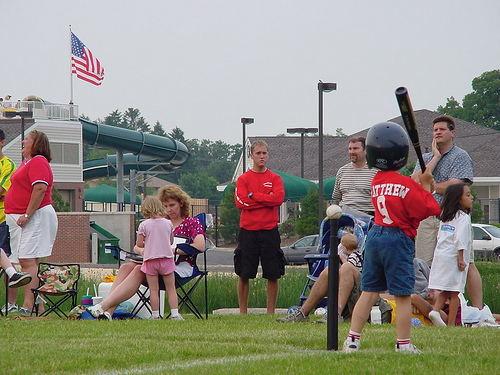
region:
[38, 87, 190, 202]
green enclosed water slide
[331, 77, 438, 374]
little boy batting ball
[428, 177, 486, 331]
little girl wearing white shirt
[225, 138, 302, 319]
teenage boy wearing long sleeve red shirt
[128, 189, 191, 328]
little girl dressed all in pink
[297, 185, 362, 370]
baseball sitting on T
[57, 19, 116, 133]
American flag waving in the air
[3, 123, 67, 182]
lady laughing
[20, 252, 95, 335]
child size camouflage chair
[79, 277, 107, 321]
reusable drinking cups with straws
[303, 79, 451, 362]
Little boy with red shirt playing T-ball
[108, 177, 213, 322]
Little girl wearing pink shirt talking to her mother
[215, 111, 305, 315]
Man standing on the side with his two arms folded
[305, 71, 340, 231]
black street light pole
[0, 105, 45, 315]
Woman standing on the side laughing so hard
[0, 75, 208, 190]
green water slide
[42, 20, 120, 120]
US flag on the top of the water slide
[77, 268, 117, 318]
water cooler on the grass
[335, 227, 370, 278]
baby standing on his fathers lap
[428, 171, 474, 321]
little girl wearing only socks without shoes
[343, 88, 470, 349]
The boy has a bat in his hand.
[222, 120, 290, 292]
The man has his hand folded.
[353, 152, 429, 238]
The boy has on a red shirt with the number 9 on it.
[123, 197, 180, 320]
the little girl has on a pink shirt and shorts.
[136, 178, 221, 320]
The lady is sitting in the chair.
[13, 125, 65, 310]
The lady in the red shirt is laughing.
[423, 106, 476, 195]
The man has his hand on his face.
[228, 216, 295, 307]
The man has on black shorts.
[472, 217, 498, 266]
A white car is parked on the side.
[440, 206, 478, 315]
The girl has on a long white tee shirt.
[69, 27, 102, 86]
American flag on a flag pole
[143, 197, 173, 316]
girl wearing pink shorts and a pink shirt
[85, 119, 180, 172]
green tube slide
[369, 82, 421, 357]
boy wearing a baseball helmet holding a bat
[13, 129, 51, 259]
woman wearing a red shirt and white shorts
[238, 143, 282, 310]
man wearing a red shirt and black shorts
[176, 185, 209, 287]
woman sitting in chair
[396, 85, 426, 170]
black baseball bat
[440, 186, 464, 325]
girl wearing a large white shirt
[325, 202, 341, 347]
tee ball stand with a baseball on top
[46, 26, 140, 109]
"The American Flag is flying"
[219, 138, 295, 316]
"The man's arms are crossed"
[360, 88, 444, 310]
"The kid is wearing a helmet"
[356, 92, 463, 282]
"The kid's shirt is red and white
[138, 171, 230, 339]
"The lady is sitting in a chair"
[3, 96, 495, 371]
"Everyone is outside in this picture"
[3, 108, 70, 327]
"The woman is laughing"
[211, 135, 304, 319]
"His shirt is red and shorts are black"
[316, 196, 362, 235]
"A white ball"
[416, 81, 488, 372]
"The man has is hand on his face"